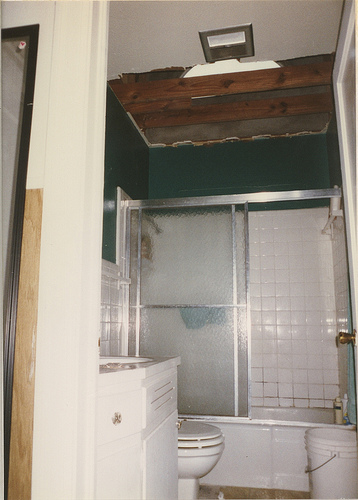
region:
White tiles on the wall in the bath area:
[245, 211, 342, 412]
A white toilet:
[175, 415, 226, 499]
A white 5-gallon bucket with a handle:
[302, 426, 356, 495]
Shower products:
[333, 391, 351, 429]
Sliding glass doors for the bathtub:
[123, 201, 269, 419]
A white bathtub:
[171, 405, 350, 489]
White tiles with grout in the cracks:
[264, 378, 325, 403]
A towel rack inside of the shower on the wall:
[310, 207, 342, 237]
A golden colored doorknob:
[330, 328, 356, 349]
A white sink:
[99, 352, 153, 370]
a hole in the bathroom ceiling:
[123, 39, 331, 161]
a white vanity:
[97, 352, 190, 492]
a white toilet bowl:
[181, 404, 215, 493]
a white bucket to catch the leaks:
[296, 412, 347, 494]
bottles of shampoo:
[321, 377, 357, 431]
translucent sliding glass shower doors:
[131, 198, 270, 410]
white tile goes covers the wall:
[260, 224, 314, 337]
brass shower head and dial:
[136, 204, 172, 268]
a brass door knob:
[330, 316, 354, 345]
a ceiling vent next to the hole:
[168, 19, 281, 65]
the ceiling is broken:
[127, 43, 337, 154]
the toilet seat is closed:
[179, 408, 232, 498]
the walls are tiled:
[256, 213, 309, 378]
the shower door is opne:
[135, 199, 351, 463]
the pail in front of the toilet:
[287, 407, 345, 494]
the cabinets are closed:
[120, 370, 203, 487]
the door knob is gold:
[316, 328, 350, 347]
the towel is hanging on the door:
[158, 291, 232, 348]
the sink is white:
[110, 349, 162, 376]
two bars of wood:
[123, 79, 328, 129]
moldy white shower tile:
[247, 208, 328, 402]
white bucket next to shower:
[295, 419, 346, 488]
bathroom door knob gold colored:
[332, 327, 355, 344]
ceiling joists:
[105, 56, 327, 129]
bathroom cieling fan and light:
[188, 16, 248, 52]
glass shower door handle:
[124, 291, 244, 298]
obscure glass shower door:
[121, 200, 244, 408]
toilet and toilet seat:
[172, 410, 222, 488]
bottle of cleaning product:
[326, 390, 338, 417]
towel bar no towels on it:
[96, 253, 131, 290]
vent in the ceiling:
[196, 31, 255, 58]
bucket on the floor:
[312, 428, 357, 493]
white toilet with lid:
[170, 424, 227, 479]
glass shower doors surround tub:
[152, 228, 258, 416]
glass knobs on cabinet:
[109, 408, 125, 434]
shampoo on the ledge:
[333, 381, 347, 427]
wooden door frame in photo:
[0, 204, 34, 493]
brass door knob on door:
[336, 328, 355, 347]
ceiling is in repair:
[112, 63, 336, 149]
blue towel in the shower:
[167, 300, 238, 325]